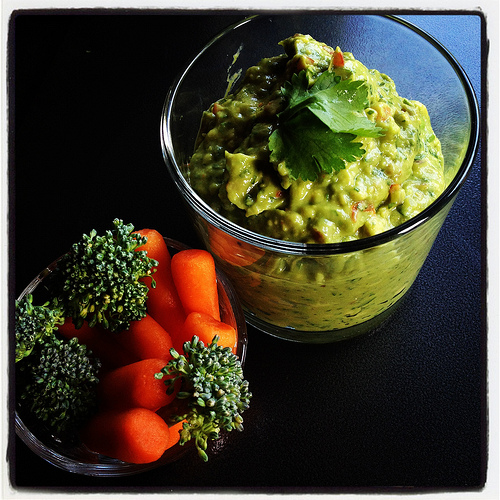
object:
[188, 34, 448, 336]
guacamole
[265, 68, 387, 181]
garnish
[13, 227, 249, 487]
small bowl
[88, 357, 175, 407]
carrot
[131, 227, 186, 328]
carrot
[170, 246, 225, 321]
carrot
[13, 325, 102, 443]
broccoli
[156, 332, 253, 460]
broccoli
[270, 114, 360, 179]
leaf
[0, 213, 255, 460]
bunch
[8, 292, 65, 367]
broccoli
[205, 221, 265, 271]
reflections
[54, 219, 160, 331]
broccoli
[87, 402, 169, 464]
baby carrots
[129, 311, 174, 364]
carrot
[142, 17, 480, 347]
glass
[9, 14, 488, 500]
table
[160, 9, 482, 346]
bowl